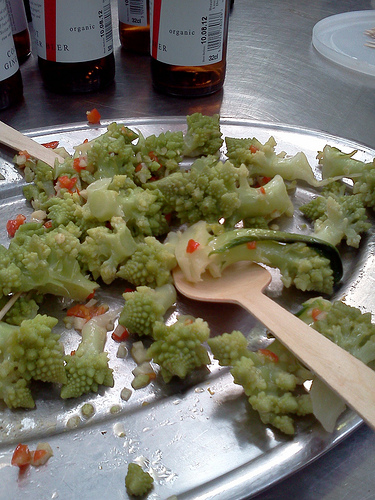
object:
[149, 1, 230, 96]
bottle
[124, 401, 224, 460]
moisture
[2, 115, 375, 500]
plate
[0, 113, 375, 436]
crabmeat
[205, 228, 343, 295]
snow pea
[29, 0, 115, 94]
bottle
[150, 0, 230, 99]
beer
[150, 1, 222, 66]
label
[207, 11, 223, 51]
bar code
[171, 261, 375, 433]
spoon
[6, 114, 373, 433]
flower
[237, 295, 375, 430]
handle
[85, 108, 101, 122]
tomato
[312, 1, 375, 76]
lid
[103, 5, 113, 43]
barcode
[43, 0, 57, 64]
stripes